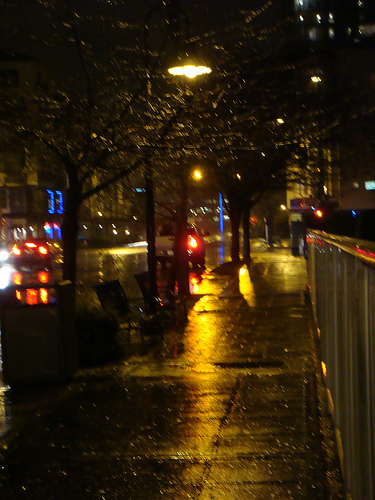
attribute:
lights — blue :
[37, 171, 74, 230]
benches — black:
[97, 252, 217, 419]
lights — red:
[177, 227, 252, 311]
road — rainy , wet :
[28, 216, 319, 455]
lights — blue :
[22, 169, 94, 280]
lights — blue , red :
[24, 157, 121, 279]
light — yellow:
[190, 163, 203, 184]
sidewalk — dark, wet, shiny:
[92, 245, 325, 495]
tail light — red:
[186, 233, 203, 249]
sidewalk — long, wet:
[133, 249, 319, 495]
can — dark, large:
[125, 262, 166, 310]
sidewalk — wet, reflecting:
[43, 253, 339, 500]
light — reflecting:
[191, 167, 203, 182]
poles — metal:
[136, 171, 164, 303]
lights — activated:
[37, 246, 50, 254]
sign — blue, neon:
[44, 186, 56, 208]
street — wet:
[8, 222, 297, 440]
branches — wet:
[92, 129, 115, 150]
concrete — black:
[40, 254, 333, 500]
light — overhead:
[187, 165, 203, 178]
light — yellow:
[190, 161, 200, 180]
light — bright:
[187, 166, 208, 180]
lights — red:
[184, 235, 207, 253]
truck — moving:
[9, 229, 66, 266]